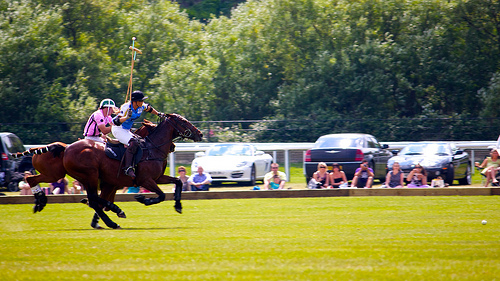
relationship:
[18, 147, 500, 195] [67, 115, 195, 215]
people watching horse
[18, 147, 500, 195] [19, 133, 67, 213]
people watching horse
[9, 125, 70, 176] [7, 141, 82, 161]
hair on tail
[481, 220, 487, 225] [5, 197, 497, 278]
ball on ground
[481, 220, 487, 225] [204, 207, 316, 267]
ball in grass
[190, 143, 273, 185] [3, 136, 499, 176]
car in parking lot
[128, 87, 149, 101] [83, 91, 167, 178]
helmet on man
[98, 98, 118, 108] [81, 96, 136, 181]
helmet on rider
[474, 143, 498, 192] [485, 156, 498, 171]
woman wearing shirt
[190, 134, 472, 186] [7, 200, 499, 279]
car facing field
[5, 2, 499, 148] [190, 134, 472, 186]
trees behind car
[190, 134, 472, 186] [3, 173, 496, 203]
car in parking lot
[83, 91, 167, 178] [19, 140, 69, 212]
man on horse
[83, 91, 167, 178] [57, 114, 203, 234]
man on horse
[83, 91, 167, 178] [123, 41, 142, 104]
man holding mallet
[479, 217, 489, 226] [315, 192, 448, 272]
ball on grass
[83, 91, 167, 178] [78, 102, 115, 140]
man wearing pink shirt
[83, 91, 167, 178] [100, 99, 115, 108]
man has head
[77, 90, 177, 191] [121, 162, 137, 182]
man has foot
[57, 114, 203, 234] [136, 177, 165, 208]
horse has leg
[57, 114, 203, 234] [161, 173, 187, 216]
horse has leg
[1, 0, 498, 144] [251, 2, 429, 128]
leaves on trees